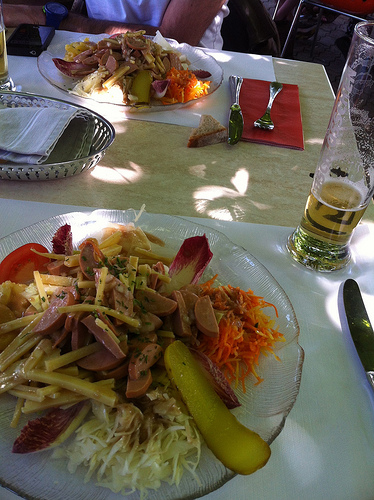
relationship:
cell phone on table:
[5, 21, 56, 58] [1, 25, 374, 500]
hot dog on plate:
[27, 265, 221, 400] [1, 207, 306, 500]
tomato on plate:
[52, 58, 94, 76] [38, 34, 225, 110]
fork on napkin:
[253, 78, 284, 131] [231, 77, 304, 150]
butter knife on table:
[228, 75, 246, 145] [1, 25, 374, 500]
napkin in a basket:
[0, 106, 96, 165] [0, 90, 116, 181]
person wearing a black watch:
[0, 0, 228, 51] [41, 1, 70, 29]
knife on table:
[342, 277, 374, 389] [1, 25, 374, 500]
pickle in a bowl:
[162, 337, 274, 476] [1, 207, 306, 500]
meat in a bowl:
[54, 27, 210, 110] [38, 34, 225, 110]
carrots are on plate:
[159, 67, 284, 394] [38, 34, 225, 110]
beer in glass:
[297, 175, 369, 248] [287, 17, 374, 275]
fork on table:
[253, 78, 284, 131] [1, 25, 374, 500]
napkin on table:
[231, 77, 304, 150] [1, 25, 374, 500]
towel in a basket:
[0, 106, 96, 165] [0, 90, 116, 181]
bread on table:
[188, 114, 230, 147] [1, 25, 374, 500]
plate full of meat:
[38, 34, 225, 110] [54, 27, 210, 110]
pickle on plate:
[162, 337, 274, 476] [1, 207, 306, 500]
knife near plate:
[228, 75, 246, 145] [38, 34, 225, 110]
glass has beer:
[287, 17, 374, 275] [297, 175, 369, 248]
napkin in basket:
[0, 106, 96, 165] [0, 90, 116, 181]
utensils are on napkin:
[227, 74, 285, 147] [231, 77, 304, 150]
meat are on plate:
[54, 27, 210, 110] [38, 34, 225, 110]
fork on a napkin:
[253, 78, 284, 131] [231, 77, 304, 150]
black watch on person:
[41, 1, 70, 29] [0, 0, 228, 51]